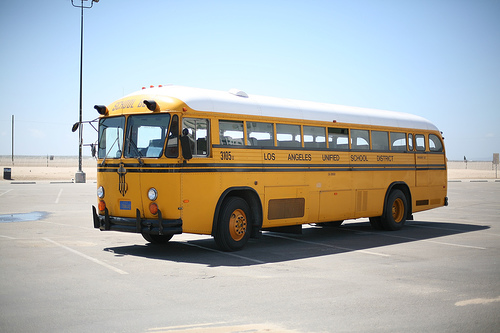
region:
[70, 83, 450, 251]
yellow school bus with a white roof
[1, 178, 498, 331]
large open parking lot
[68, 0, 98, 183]
tall pole with safety lights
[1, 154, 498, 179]
field of tan sandy soil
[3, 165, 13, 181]
black metal drum trash can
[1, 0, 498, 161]
clear cloudless light blue sky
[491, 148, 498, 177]
white street sign on a metal pole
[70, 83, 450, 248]
a vintage yellow school bus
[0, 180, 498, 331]
a paved parking lot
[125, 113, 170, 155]
a bus front windshield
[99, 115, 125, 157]
a bus front windshield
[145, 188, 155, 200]
a bus front headlight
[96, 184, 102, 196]
a bus front headlight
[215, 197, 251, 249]
a bus front tire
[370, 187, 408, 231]
a bus front tire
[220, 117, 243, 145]
a school bus window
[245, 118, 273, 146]
a school bus window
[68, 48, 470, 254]
this is a bus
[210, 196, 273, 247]
a wheel on a bus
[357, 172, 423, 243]
a wheel on a bus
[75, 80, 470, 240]
the bus is yellow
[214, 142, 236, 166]
letters on the bus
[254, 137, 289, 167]
a word on the bus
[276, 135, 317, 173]
a word on the bus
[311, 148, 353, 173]
a word on the bus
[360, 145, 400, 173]
a word on the bus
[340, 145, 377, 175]
a word on the bus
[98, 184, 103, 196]
The left headlight of the bus.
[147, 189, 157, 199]
The right headlight of the bus.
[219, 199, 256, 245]
The front right tire.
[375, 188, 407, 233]
The back right tire.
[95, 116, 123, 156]
The left front window.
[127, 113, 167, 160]
The right front window.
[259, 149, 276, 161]
The word Los on the side of the bus.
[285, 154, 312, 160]
The word Angeles on the side of the bus.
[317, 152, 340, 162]
The word Unified on the side of the bus.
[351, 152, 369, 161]
The word School on the side of the bus.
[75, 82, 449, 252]
yellow and black school bus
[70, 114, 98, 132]
right side mirror of a bus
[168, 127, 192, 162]
driver side view mirror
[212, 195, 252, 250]
large black rubber wheels with yellow rims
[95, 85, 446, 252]
two black stripes on a bus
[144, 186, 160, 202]
round shiny head light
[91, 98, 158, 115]
two black light fixtures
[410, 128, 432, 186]
emergency exit door of a bus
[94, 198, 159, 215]
two circular reflectors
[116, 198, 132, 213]
blue and yellow license plate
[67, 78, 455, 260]
large yellow school bus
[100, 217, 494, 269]
shadow beneath school bus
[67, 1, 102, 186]
tall metal lightpost